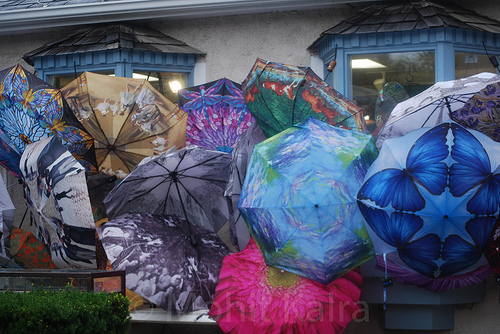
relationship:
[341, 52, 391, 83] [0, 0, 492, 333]
light inside building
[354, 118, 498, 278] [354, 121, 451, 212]
umbrella has butterlfy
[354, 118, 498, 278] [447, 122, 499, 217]
umbrella has butterlfy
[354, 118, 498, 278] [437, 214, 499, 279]
umbrella has butterlfy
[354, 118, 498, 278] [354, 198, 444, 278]
umbrella has butterlfy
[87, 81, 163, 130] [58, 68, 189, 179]
humans on umbrella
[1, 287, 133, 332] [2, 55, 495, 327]
bush next to umbrellas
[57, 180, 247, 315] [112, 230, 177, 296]
umbrella has image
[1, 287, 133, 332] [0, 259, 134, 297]
bush below glass case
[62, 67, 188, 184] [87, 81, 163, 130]
brownumbrella with humans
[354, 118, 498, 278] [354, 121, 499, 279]
umbrella with motifs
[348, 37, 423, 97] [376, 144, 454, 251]
window behind umbrella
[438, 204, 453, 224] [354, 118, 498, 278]
black dot on umbrella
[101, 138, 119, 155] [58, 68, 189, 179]
black dot on umbrella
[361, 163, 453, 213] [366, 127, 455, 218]
butterfly on umbrella